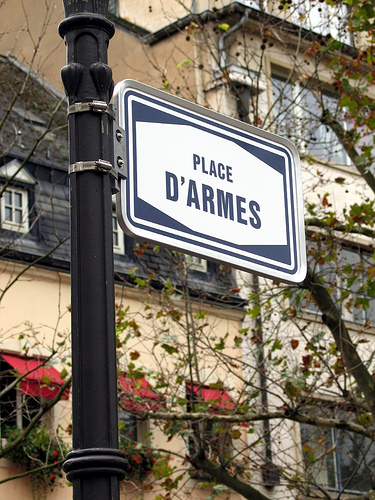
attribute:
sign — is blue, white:
[116, 76, 323, 289]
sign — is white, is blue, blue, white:
[111, 80, 309, 283]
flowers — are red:
[289, 339, 299, 349]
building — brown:
[1, 0, 373, 499]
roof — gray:
[1, 91, 67, 152]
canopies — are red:
[15, 348, 258, 413]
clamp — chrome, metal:
[58, 89, 127, 184]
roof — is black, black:
[0, 53, 250, 312]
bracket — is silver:
[65, 99, 113, 117]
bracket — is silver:
[68, 159, 115, 174]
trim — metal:
[119, 73, 310, 156]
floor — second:
[253, 191, 364, 330]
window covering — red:
[0, 349, 68, 402]